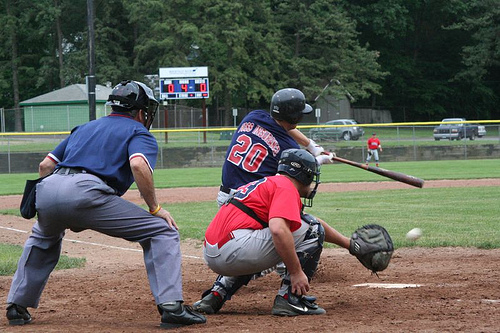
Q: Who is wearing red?
A: Catcher.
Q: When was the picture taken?
A: Daytime.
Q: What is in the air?
A: Baseball.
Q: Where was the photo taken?
A: At a baseball game.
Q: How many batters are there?
A: One.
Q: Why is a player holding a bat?
A: To hit a ball.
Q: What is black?
A: Baseball glove.